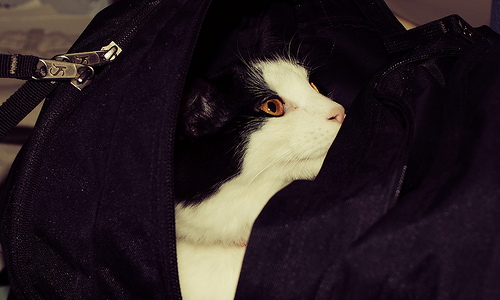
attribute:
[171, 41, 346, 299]
cat — black, white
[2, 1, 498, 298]
bag — black, purple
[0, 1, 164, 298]
zipper — silver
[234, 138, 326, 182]
whiskers — white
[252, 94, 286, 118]
eye — orange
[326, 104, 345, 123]
nose — pink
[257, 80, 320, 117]
eyes — orange, yellow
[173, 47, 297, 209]
hair — black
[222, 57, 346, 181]
face — white